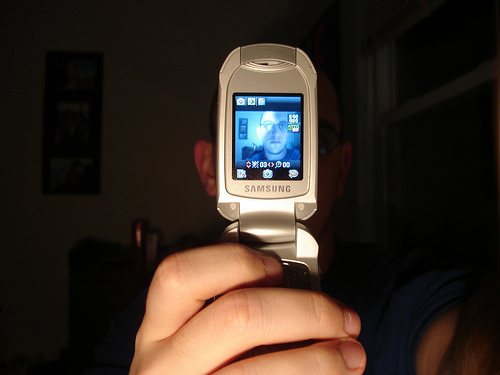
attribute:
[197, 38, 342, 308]
cell phone — flipped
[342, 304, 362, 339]
nails — finger tips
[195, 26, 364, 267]
phone — selfie , flip top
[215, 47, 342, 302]
phone — silver, Samsung, flip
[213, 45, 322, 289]
phone — company, name, screen, man's face 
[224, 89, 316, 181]
screen — lcd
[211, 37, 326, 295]
flip phone — open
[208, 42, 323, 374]
phone —  part 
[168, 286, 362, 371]
finger —  part 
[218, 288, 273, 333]
knuckle —  middle 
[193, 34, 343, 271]
phone —  camera ,  cell 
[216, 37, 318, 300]
phone — silver surface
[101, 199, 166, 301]
light — distance.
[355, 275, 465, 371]
sleeve —  blue shirt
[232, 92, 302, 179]
screen —  edge 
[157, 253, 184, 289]
knuckle — white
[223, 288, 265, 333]
knuckle — white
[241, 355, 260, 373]
knuckle — white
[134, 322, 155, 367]
knuckle — white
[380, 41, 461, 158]
frame — white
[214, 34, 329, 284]
phone —  open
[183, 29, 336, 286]
picture —  himself 